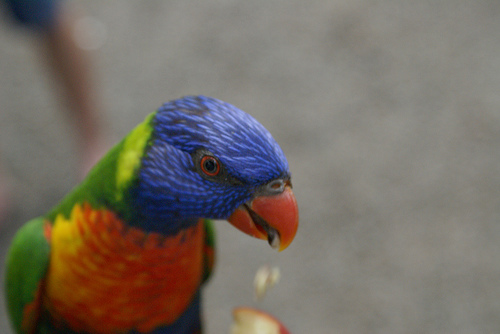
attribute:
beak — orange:
[228, 185, 298, 251]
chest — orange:
[81, 230, 187, 300]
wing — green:
[1, 222, 53, 329]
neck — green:
[82, 127, 154, 219]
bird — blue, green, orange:
[13, 98, 330, 325]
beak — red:
[223, 186, 314, 261]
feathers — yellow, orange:
[52, 221, 195, 313]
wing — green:
[5, 203, 62, 331]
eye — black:
[198, 153, 220, 178]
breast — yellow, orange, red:
[55, 203, 204, 322]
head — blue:
[142, 91, 299, 252]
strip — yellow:
[115, 111, 153, 204]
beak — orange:
[238, 175, 295, 252]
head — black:
[148, 97, 337, 261]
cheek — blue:
[135, 148, 216, 226]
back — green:
[39, 143, 122, 223]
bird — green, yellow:
[3, 90, 297, 327]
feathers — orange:
[45, 203, 201, 332]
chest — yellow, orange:
[50, 211, 200, 321]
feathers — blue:
[139, 93, 291, 223]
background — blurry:
[297, 75, 427, 232]